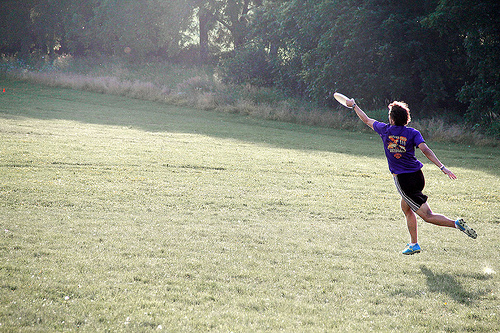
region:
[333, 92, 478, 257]
Man stretching arm to catch frisbee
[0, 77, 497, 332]
Open grass field daytime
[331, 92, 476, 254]
Man wearing shorts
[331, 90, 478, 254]
Athlete wearing shoes with spikes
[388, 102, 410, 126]
Sunlight in man's hair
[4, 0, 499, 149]
Tree line on a green field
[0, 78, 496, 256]
Playing on a field during the day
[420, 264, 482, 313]
Man's shadow on the field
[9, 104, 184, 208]
Short cut grass in a field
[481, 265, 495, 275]
Shiny object in field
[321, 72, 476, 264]
a guy catching a frisbee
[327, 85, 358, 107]
a single white toy frisbee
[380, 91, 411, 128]
the head of an adult man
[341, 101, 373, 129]
the arm of an adult man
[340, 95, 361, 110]
a hand catching a frisbee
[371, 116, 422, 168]
a dark purple t shirt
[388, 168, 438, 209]
a pair of tight black shorts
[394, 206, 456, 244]
the legs of an adult man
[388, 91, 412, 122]
a lot of curly brown hair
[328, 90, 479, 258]
man leaping in the air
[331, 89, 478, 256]
man holding a white frisbee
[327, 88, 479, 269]
man catching a white frisbee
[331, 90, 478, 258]
man in a purple shirt catching a frisbee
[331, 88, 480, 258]
man playing frisbee wearing blue cleats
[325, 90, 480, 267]
man off the ground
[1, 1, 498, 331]
man on a large grassy field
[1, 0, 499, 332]
grassy field lined with trees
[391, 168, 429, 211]
black and white shorts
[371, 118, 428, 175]
purple shirt with a colorful back graphic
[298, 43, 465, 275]
a man catching a frisbee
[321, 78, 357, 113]
a white frisbee disk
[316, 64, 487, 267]
a man slightly off the ground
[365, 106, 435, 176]
a man wearing a purple tshirt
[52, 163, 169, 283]
well groomed green grass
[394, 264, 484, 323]
a man's shadow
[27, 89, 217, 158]
shadows thrown by a line of trees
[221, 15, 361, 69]
a copse of leafy green trees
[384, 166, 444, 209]
a pair of black striped athletic shorts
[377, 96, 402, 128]
man has brown hair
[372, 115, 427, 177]
man has blue shirt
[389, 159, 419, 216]
black and white shorts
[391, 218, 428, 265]
man has blue shoes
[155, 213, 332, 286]
grass is light green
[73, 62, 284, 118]
brown and green grass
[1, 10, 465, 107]
thick green trees behind grasses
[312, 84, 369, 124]
man holds white frisbee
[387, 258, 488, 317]
man has short shadow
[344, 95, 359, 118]
man is wearing watch on left hand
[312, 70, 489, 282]
Person reaching out to grab the white disk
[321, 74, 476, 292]
Man wearing cleats to give himself more balance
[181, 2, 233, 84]
A tree in the woods.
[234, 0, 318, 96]
A tree in the woods.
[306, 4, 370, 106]
A tree in the woods.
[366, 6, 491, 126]
A tree in the woods.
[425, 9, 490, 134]
A tree in the woods.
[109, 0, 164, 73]
A tree in the woods.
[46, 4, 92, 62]
A tree in the woods.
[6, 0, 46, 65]
A tree in the woods.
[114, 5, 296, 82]
A tree in the woods.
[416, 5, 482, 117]
A tree in the woods.